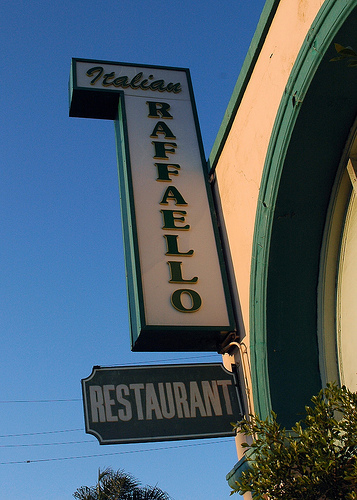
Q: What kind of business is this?
A: Restaurant.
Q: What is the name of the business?
A: Italian Raffaello.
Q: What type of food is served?
A: Italian.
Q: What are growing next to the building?
A: Trees.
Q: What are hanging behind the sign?
A: Wires.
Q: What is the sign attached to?
A: Building.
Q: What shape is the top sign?
A: L.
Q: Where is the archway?
A: On the building.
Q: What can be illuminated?
A: Sign.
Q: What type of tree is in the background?
A: Palm.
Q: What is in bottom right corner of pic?
A: Green bush in front of a restaurant.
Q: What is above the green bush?
A: Restaurant sign is visible.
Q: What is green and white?
A: Restaurant sign is visible.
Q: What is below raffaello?
A: Restaurant sign is visible.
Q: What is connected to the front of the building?
A: Restaurant sign is visible.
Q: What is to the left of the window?
A: Restaurant sign is visible.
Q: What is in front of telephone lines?
A: Restaurant sign is visible.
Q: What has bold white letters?
A: A restaurant sign is visible.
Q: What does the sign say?
A: Italian Raffaello.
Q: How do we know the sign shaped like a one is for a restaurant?
A: There is a green, horizontal sign below it, reading, "restaurant".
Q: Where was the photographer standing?
A: In front of, and below the signs.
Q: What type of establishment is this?
A: Restaurant.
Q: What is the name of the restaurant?
A: Raffaello.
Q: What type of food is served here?
A: Italian.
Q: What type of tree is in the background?
A: Palm.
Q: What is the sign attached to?
A: Restaurant.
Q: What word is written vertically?
A: Raffaello.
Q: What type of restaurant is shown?
A: Italian.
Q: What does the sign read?
A: Italian Raffaello restaurant.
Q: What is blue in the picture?
A: Sky.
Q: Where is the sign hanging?
A: Outside building.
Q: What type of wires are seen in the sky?
A: Electrical.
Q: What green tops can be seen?
A: Trees.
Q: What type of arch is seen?
A: Green.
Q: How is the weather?
A: Sunny.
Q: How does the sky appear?
A: Cloudless.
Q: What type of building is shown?
A: A restaurant.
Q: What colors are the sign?
A: Green, white.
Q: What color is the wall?
A: Peach.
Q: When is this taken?
A: Daytime.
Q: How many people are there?
A: 0.